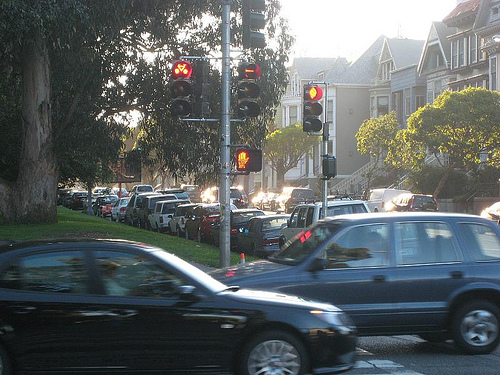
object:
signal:
[229, 144, 265, 178]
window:
[285, 202, 314, 227]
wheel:
[461, 306, 498, 350]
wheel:
[251, 327, 293, 364]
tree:
[404, 86, 498, 194]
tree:
[387, 127, 427, 193]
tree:
[356, 111, 396, 189]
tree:
[267, 125, 314, 189]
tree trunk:
[14, 44, 68, 224]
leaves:
[92, 28, 159, 98]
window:
[319, 204, 367, 221]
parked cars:
[58, 180, 375, 253]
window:
[21, 246, 90, 301]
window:
[243, 216, 262, 235]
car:
[210, 207, 255, 244]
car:
[146, 197, 191, 236]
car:
[107, 197, 132, 221]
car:
[207, 212, 499, 354]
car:
[280, 192, 372, 253]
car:
[239, 209, 289, 252]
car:
[218, 203, 265, 245]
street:
[151, 172, 389, 261]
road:
[369, 343, 458, 371]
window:
[320, 223, 392, 269]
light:
[297, 80, 324, 133]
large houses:
[334, 20, 470, 162]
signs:
[171, 20, 264, 242]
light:
[170, 56, 193, 120]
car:
[2, 223, 360, 374]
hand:
[232, 148, 253, 171]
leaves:
[354, 106, 402, 154]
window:
[101, 238, 185, 305]